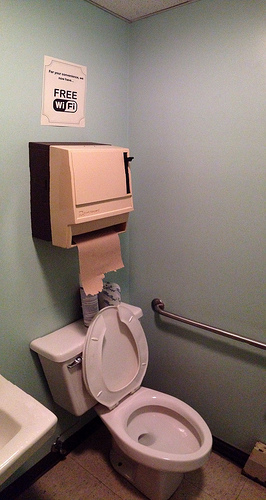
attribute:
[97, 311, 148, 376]
lid — up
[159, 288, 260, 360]
bar — silver 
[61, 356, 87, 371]
handle — silver 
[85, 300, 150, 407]
lid — open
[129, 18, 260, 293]
wall — green 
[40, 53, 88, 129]
sign — white 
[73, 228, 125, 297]
paper towel — brown 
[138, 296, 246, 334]
handle — silver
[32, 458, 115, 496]
floor — tiled 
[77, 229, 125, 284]
paper — brown 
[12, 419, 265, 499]
floor — tiled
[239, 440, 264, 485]
box — brown 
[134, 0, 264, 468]
wall — green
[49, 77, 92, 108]
word — free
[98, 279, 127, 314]
toilet paper — roll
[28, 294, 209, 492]
toilet — clean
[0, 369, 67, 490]
bathroom sink — white 